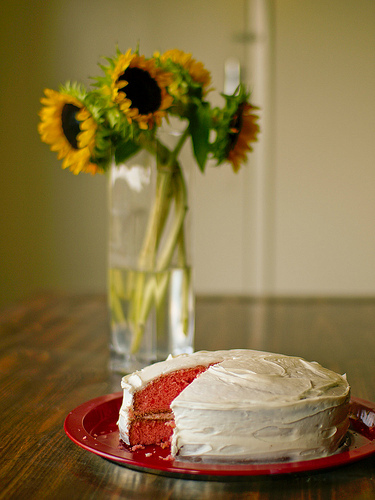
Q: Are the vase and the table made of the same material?
A: No, the vase is made of glass and the table is made of wood.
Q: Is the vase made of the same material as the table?
A: No, the vase is made of glass and the table is made of wood.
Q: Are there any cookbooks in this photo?
A: No, there are no cookbooks.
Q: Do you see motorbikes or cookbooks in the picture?
A: No, there are no cookbooks or motorbikes.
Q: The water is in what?
A: The water is in the vase.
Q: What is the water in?
A: The water is in the vase.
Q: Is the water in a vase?
A: Yes, the water is in a vase.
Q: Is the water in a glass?
A: No, the water is in a vase.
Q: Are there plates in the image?
A: Yes, there is a plate.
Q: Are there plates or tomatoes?
A: Yes, there is a plate.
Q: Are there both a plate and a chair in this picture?
A: No, there is a plate but no chairs.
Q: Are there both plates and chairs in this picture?
A: No, there is a plate but no chairs.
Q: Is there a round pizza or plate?
A: Yes, there is a round plate.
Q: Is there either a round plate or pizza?
A: Yes, there is a round plate.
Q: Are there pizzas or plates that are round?
A: Yes, the plate is round.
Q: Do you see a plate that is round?
A: Yes, there is a round plate.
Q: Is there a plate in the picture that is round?
A: Yes, there is a plate that is round.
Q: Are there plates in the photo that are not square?
A: Yes, there is a round plate.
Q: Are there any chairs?
A: No, there are no chairs.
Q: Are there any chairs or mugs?
A: No, there are no chairs or mugs.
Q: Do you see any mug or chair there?
A: No, there are no chairs or mugs.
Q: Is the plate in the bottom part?
A: Yes, the plate is in the bottom of the image.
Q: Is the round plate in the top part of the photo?
A: No, the plate is in the bottom of the image.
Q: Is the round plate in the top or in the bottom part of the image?
A: The plate is in the bottom of the image.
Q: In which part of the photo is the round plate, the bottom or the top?
A: The plate is in the bottom of the image.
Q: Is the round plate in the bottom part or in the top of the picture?
A: The plate is in the bottom of the image.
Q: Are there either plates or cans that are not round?
A: No, there is a plate but it is round.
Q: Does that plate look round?
A: Yes, the plate is round.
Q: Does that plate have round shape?
A: Yes, the plate is round.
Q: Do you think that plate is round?
A: Yes, the plate is round.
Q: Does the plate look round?
A: Yes, the plate is round.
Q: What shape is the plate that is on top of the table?
A: The plate is round.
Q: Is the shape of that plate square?
A: No, the plate is round.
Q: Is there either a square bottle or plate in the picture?
A: No, there is a plate but it is round.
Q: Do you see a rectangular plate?
A: No, there is a plate but it is round.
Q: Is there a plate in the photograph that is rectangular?
A: No, there is a plate but it is round.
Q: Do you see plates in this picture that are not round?
A: No, there is a plate but it is round.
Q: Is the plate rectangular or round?
A: The plate is round.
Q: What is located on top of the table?
A: The plate is on top of the table.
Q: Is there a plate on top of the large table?
A: Yes, there is a plate on top of the table.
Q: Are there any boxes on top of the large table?
A: No, there is a plate on top of the table.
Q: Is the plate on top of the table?
A: Yes, the plate is on top of the table.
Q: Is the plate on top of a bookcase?
A: No, the plate is on top of the table.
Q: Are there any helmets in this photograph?
A: No, there are no helmets.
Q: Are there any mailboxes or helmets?
A: No, there are no helmets or mailboxes.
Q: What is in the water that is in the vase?
A: The sunflowers are in the water.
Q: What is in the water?
A: The sunflowers are in the water.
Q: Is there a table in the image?
A: Yes, there is a table.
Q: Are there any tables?
A: Yes, there is a table.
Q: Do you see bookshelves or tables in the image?
A: Yes, there is a table.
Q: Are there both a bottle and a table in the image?
A: No, there is a table but no bottles.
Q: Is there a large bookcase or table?
A: Yes, there is a large table.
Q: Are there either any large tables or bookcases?
A: Yes, there is a large table.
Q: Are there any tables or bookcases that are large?
A: Yes, the table is large.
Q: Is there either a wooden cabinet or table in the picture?
A: Yes, there is a wood table.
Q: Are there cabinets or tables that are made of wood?
A: Yes, the table is made of wood.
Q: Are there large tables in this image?
A: Yes, there is a large table.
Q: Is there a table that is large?
A: Yes, there is a table that is large.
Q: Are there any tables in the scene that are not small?
A: Yes, there is a large table.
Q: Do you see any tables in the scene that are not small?
A: Yes, there is a large table.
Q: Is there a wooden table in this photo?
A: Yes, there is a wood table.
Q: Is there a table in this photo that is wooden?
A: Yes, there is a table that is wooden.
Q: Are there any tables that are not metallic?
A: Yes, there is a wooden table.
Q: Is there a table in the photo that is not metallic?
A: Yes, there is a wooden table.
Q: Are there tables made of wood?
A: Yes, there is a table that is made of wood.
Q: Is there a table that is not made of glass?
A: Yes, there is a table that is made of wood.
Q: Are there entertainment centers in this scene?
A: No, there are no entertainment centers.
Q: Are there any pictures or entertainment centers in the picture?
A: No, there are no entertainment centers or pictures.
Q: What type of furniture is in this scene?
A: The furniture is a table.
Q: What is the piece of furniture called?
A: The piece of furniture is a table.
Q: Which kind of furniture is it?
A: The piece of furniture is a table.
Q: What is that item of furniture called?
A: That is a table.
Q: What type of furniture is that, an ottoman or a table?
A: That is a table.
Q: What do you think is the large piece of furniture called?
A: The piece of furniture is a table.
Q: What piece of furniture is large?
A: The piece of furniture is a table.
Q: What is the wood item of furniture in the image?
A: The piece of furniture is a table.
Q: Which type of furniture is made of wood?
A: The furniture is a table.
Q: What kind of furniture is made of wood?
A: The furniture is a table.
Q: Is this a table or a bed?
A: This is a table.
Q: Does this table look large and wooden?
A: Yes, the table is large and wooden.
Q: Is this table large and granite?
A: No, the table is large but wooden.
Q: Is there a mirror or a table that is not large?
A: No, there is a table but it is large.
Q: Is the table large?
A: Yes, the table is large.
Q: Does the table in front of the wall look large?
A: Yes, the table is large.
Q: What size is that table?
A: The table is large.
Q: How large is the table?
A: The table is large.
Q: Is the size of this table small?
A: No, the table is large.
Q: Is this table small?
A: No, the table is large.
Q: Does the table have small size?
A: No, the table is large.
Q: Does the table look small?
A: No, the table is large.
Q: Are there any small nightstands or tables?
A: No, there is a table but it is large.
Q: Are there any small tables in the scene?
A: No, there is a table but it is large.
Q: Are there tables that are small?
A: No, there is a table but it is large.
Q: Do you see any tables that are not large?
A: No, there is a table but it is large.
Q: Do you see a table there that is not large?
A: No, there is a table but it is large.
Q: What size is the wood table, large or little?
A: The table is large.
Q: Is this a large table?
A: Yes, this is a large table.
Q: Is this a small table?
A: No, this is a large table.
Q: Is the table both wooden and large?
A: Yes, the table is wooden and large.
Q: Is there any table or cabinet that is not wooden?
A: No, there is a table but it is wooden.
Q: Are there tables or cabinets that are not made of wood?
A: No, there is a table but it is made of wood.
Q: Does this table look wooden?
A: Yes, the table is wooden.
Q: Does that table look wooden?
A: Yes, the table is wooden.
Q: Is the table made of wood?
A: Yes, the table is made of wood.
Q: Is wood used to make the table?
A: Yes, the table is made of wood.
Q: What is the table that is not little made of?
A: The table is made of wood.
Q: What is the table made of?
A: The table is made of wood.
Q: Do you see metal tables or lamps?
A: No, there is a table but it is wooden.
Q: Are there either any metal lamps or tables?
A: No, there is a table but it is wooden.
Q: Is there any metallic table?
A: No, there is a table but it is wooden.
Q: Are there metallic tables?
A: No, there is a table but it is wooden.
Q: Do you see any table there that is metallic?
A: No, there is a table but it is wooden.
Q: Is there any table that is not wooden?
A: No, there is a table but it is wooden.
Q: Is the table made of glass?
A: No, the table is made of wood.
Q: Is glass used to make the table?
A: No, the table is made of wood.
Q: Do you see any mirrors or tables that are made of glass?
A: No, there is a table but it is made of wood.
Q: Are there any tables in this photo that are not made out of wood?
A: No, there is a table but it is made of wood.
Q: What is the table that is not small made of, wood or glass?
A: The table is made of wood.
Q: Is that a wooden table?
A: Yes, that is a wooden table.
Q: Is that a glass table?
A: No, that is a wooden table.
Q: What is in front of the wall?
A: The table is in front of the wall.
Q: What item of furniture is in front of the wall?
A: The piece of furniture is a table.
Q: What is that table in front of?
A: The table is in front of the wall.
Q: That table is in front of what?
A: The table is in front of the wall.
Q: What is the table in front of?
A: The table is in front of the wall.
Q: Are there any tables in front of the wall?
A: Yes, there is a table in front of the wall.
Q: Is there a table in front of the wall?
A: Yes, there is a table in front of the wall.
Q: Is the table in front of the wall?
A: Yes, the table is in front of the wall.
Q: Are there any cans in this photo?
A: No, there are no cans.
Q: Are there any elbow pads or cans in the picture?
A: No, there are no cans or elbow pads.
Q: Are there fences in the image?
A: No, there are no fences.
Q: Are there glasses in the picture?
A: No, there are no glasses.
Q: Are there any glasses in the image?
A: No, there are no glasses.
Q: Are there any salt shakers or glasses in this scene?
A: No, there are no glasses or salt shakers.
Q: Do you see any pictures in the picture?
A: No, there are no pictures.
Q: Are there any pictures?
A: No, there are no pictures.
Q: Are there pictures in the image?
A: No, there are no pictures.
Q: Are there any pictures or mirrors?
A: No, there are no pictures or mirrors.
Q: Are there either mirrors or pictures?
A: No, there are no pictures or mirrors.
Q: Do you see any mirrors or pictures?
A: No, there are no pictures or mirrors.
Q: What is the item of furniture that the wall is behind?
A: The piece of furniture is a table.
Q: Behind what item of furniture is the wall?
A: The wall is behind the table.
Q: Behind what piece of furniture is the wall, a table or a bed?
A: The wall is behind a table.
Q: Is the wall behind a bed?
A: No, the wall is behind a table.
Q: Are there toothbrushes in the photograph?
A: No, there are no toothbrushes.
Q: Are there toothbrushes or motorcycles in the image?
A: No, there are no toothbrushes or motorcycles.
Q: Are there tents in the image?
A: No, there are no tents.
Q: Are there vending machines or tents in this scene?
A: No, there are no tents or vending machines.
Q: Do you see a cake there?
A: Yes, there is a cake.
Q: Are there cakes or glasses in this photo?
A: Yes, there is a cake.